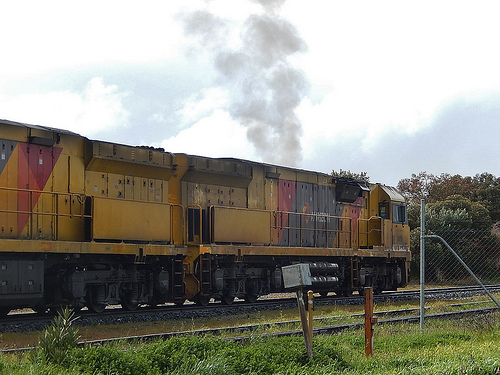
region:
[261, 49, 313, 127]
THAT IS SMOKE IN THE AIR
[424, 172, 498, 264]
THESE ARE SOME TREES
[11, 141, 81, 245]
THIS IS A TARIN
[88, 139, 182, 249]
THIS IS A TARIN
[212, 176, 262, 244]
THIS IS A TARIN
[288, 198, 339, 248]
THIS IS A TARIN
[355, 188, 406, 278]
THIS IS A TARIN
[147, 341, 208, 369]
THE GRASS IS FRESH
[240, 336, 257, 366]
THE GRASS IS FRESH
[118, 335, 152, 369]
THE GRASS IS FRESH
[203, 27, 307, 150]
steam coming out of the train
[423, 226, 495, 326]
a chain link fence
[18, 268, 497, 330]
the rail road tracks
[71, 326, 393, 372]
grass next to the train tracks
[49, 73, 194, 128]
clouds in the sky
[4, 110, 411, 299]
a yellow train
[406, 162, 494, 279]
trees in the distance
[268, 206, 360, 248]
a fence on the train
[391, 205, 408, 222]
a window on the train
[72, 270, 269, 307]
the wheels on the train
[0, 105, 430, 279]
the train on the tracks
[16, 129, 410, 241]
the train is yellow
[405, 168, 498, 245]
trees beside the tracks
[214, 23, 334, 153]
smoke above the train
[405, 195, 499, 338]
fence beside the track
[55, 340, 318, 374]
grass beside the tracks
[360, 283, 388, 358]
the post in the grass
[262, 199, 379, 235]
railing on the train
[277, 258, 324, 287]
metal box on a pole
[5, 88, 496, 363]
The train is on the railroad tracks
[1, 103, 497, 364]
The train is carrying some cargo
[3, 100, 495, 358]
The train is headed to the city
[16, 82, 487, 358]
The locomotive is pulling many cars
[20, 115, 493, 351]
The locomotive has a powerful engine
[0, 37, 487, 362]
The train is traveling in daytime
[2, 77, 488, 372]
The train is passing some trees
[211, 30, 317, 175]
black smoke behind the train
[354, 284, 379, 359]
post in the ground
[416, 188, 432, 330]
metal pole at the corner of the fence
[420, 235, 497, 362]
chain link fence by the tracks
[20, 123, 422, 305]
train on the tracks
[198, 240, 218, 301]
steps going up to the train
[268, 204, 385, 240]
railing along the train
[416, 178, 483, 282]
trees on the other side of the tracks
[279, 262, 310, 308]
metal box on a post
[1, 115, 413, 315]
train is on the track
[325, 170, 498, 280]
trees are in front of the tracks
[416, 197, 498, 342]
fence is beside the train tracks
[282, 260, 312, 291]
a small white box